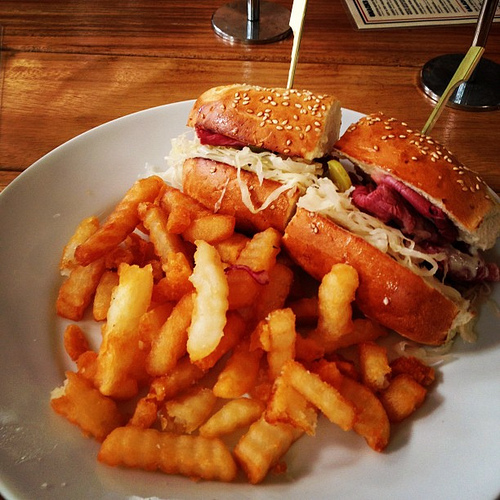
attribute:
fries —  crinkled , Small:
[45, 233, 233, 445]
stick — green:
[411, 1, 491, 127]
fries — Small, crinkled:
[45, 169, 443, 486]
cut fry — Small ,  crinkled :
[198, 394, 263, 446]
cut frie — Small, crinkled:
[311, 259, 356, 344]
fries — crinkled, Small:
[160, 291, 362, 391]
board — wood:
[1, 0, 498, 65]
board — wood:
[0, 47, 498, 188]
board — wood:
[0, 172, 20, 191]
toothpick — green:
[420, 45, 485, 135]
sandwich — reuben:
[189, 107, 474, 247]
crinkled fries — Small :
[57, 242, 413, 485]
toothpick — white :
[434, 47, 475, 142]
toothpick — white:
[280, 8, 329, 108]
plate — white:
[4, 80, 496, 497]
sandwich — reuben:
[0, 76, 490, 498]